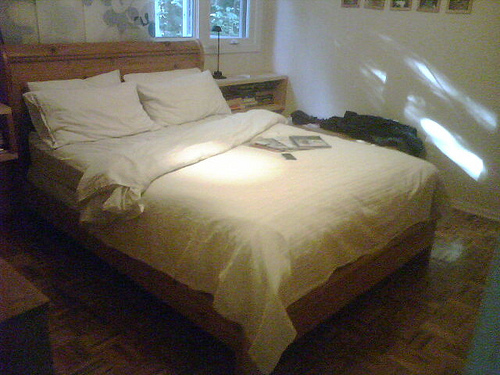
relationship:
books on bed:
[247, 135, 332, 153] [1, 36, 447, 372]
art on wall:
[337, 0, 472, 19] [273, 2, 484, 212]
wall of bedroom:
[273, 2, 484, 212] [5, 2, 484, 349]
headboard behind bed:
[2, 33, 207, 139] [1, 36, 447, 372]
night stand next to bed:
[216, 69, 293, 119] [1, 36, 447, 372]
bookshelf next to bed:
[221, 72, 309, 122] [1, 36, 447, 372]